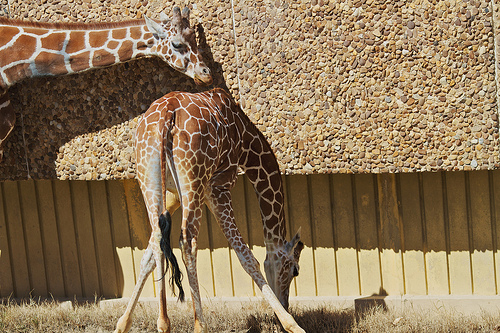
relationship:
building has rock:
[300, 12, 475, 213] [402, 57, 463, 116]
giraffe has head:
[65, 67, 368, 333] [236, 228, 331, 305]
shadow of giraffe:
[336, 276, 392, 328] [65, 67, 368, 333]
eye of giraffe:
[281, 257, 312, 293] [65, 67, 368, 333]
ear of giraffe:
[261, 211, 313, 274] [65, 67, 368, 333]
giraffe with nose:
[65, 67, 368, 333] [275, 279, 304, 318]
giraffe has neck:
[65, 67, 368, 333] [213, 129, 319, 225]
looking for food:
[65, 67, 368, 333] [265, 289, 318, 329]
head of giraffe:
[236, 228, 331, 305] [65, 67, 368, 333]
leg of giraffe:
[97, 202, 169, 309] [65, 67, 368, 333]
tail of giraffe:
[139, 130, 192, 228] [65, 67, 368, 333]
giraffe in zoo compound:
[65, 67, 368, 333] [1, 1, 484, 330]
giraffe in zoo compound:
[0, 1, 215, 146] [1, 1, 484, 330]